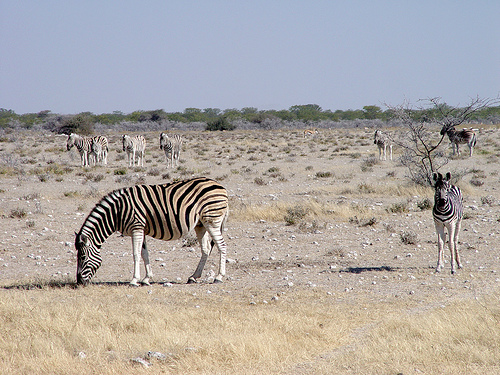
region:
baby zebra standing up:
[432, 172, 462, 272]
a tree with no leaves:
[385, 95, 491, 193]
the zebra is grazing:
[74, 178, 228, 286]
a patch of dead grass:
[18, 293, 498, 373]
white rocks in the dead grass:
[130, 345, 196, 368]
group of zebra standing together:
[65, 130, 187, 164]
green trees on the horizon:
[2, 106, 495, 128]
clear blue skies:
[2, 4, 495, 113]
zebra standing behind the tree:
[440, 124, 478, 154]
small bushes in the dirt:
[265, 164, 282, 179]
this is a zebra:
[55, 171, 255, 305]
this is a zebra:
[417, 143, 478, 294]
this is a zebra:
[431, 91, 481, 173]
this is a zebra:
[347, 105, 388, 187]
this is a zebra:
[142, 111, 207, 209]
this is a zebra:
[60, 131, 107, 192]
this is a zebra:
[102, 122, 153, 187]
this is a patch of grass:
[242, 298, 326, 372]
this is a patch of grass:
[332, 301, 470, 361]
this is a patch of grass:
[47, 306, 179, 354]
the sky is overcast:
[47, 40, 425, 116]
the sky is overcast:
[70, 25, 332, 92]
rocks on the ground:
[264, 252, 378, 312]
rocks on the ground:
[239, 185, 359, 310]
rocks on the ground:
[234, 210, 427, 319]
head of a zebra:
[70, 212, 119, 282]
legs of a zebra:
[119, 234, 242, 282]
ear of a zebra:
[62, 234, 96, 250]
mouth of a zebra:
[64, 268, 108, 293]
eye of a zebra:
[74, 255, 89, 266]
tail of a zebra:
[213, 206, 243, 242]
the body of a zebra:
[126, 174, 241, 241]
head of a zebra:
[420, 163, 461, 209]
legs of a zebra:
[417, 229, 472, 281]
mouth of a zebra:
[437, 191, 450, 205]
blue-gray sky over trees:
[1, 1, 491, 121]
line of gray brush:
[0, 120, 495, 126]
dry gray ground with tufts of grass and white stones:
[1, 130, 491, 295]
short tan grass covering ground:
[5, 285, 495, 370]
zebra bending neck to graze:
[66, 175, 231, 287]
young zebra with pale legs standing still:
[416, 165, 461, 271]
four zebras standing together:
[60, 125, 181, 170]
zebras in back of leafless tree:
[366, 100, 477, 165]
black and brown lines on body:
[125, 176, 225, 236]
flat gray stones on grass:
[107, 332, 174, 370]